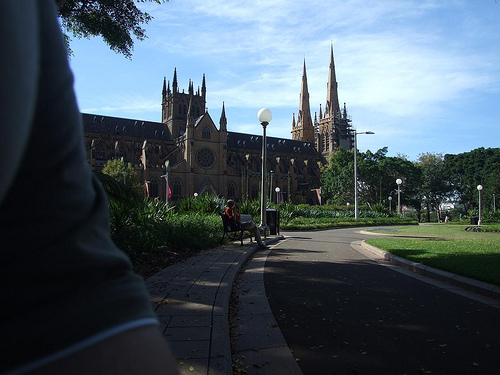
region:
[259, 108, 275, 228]
The light pole next to the bench.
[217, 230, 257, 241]
The legs of the bench.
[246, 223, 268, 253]
The legs of the person sitting on the bench.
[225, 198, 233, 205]
The head of the person on the bench.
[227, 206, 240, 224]
The shirt the person on the bench is wearing.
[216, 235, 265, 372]
The curb of the sidewalk on the left.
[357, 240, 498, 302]
The curb of the grass area on the right.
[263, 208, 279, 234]
The trash can near the lamp post.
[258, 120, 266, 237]
The pole of the lamp post.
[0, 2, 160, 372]
Person wearing a shirt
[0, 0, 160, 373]
Person is wearing a shirt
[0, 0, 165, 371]
Person wearing a gray shirt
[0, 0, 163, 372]
Person is wearing a gray shirt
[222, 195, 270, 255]
Person on a bench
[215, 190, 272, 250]
Person is on a bench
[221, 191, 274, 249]
Person sitting down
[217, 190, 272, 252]
Person is sitting down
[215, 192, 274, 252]
Person sitting down on a bench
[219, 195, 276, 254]
Person is sitting down on a bench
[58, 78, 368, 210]
large building in distance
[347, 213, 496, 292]
green grass near road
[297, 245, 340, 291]
road is dark grey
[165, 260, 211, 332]
sidewalk is light grey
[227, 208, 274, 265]
man sitting on bench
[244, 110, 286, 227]
light pole behind man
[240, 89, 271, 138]
white globe lamp on pole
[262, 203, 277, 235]
trash bin near pole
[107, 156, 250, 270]
green bushes behind man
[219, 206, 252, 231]
man has red shirt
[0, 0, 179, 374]
Arm of a person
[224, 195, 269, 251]
Person sitting on a bench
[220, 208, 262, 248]
Bench on a sidewalk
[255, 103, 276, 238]
White globe street lamp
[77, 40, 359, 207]
Large decorative brown building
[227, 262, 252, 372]
Leaves along a curb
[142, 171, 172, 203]
Two flags on a pole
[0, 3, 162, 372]
Dark and white shirt sleeve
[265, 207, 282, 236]
Black metal trashcan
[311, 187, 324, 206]
Triangular flag on a pole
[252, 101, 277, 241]
A tall street lamp.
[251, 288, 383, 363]
Leaves scattered on the pavement.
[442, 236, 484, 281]
Green grass near a curb.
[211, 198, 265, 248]
A man sitting on a bench.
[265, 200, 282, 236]
A small green wastebasket.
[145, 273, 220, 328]
A square pattern on the sidewalk.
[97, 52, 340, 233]
A large abbey in the background.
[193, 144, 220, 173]
A circular design inset into the abbey.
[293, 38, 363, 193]
Two large towers with spires.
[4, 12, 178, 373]
The gray shirt of a person in the foreground.